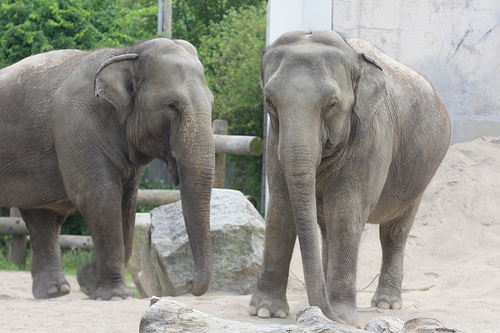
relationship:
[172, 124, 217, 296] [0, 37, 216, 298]
trunk of elephant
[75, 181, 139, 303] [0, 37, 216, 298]
front legs of elephant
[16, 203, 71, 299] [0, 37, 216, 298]
back leg of elephant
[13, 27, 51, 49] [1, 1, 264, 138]
leaves are on trees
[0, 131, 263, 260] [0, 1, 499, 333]
fence of zoo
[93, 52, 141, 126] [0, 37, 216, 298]
ear on elephant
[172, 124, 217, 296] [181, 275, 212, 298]
trunk curled at end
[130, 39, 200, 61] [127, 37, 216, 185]
lumps are on head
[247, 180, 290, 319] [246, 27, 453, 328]
leg of elephant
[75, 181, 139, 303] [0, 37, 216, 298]
leg of elephant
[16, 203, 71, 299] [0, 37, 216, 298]
leg of elephant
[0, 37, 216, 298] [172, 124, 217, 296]
elephant has trunk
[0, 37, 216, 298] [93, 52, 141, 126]
elephant has ear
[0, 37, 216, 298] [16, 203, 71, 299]
elephant has leg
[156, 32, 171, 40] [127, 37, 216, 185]
hair on head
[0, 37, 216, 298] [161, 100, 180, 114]
elephant has eyes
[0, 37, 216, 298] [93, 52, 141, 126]
elephant has ears